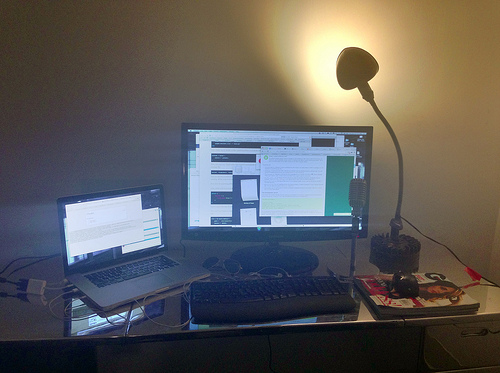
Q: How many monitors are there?
A: Two.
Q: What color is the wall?
A: Yellow.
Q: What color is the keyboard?
A: Black.